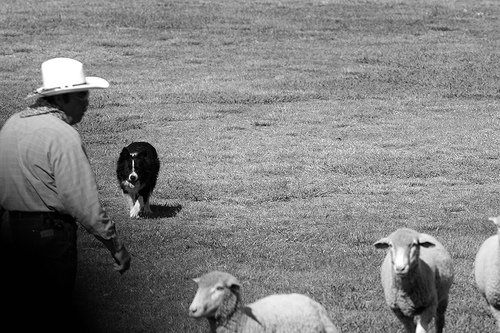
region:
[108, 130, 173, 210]
dog in the field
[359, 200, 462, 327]
sheep in the field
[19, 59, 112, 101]
man wearing a hat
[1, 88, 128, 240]
man wearing a dress shirt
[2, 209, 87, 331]
man wearing black pants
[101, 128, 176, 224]
black dog in the field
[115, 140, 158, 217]
A black dog with white legs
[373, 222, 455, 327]
A white sheep in a field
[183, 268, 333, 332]
A white sheep in a field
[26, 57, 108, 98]
A white hat on a man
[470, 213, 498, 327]
A white sheep in a field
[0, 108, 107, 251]
A long sleeved shirt on a man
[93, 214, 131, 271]
A glove on a man's hand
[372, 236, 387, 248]
Ear on a sheep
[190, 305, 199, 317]
A nose on a sheep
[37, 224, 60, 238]
A tag on a man's pants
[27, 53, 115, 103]
A hat in the photo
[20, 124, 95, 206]
A plaid shirt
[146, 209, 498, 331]
A sheep in the field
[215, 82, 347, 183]
grass in the photo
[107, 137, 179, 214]
A dog in the photo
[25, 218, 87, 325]
Black pants in the photo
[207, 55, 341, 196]
Grass in the field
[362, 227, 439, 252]
Ears of the sheep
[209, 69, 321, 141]
Grass in the background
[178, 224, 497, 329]
Sheep in the foreground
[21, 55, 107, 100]
A cowboy hat on the man's head.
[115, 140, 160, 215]
A sheepdog walking.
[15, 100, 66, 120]
A bandanna around the man's neck.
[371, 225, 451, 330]
A sheep walking.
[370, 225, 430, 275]
The sheep's head.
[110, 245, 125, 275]
The man's right hand.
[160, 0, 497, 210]
A grassy field behind the animals.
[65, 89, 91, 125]
The man's face.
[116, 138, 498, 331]
The dog following the sheep.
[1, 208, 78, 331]
The man's pants.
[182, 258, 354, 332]
white sheep standing in front of man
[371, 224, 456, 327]
sheep in front of man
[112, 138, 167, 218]
black and white dog herding sheep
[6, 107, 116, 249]
man wearing white shirt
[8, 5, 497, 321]
large expanse of grassy field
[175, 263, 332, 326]
sheep has been shorn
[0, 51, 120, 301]
man wearing a hat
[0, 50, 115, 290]
man wearing a shirt